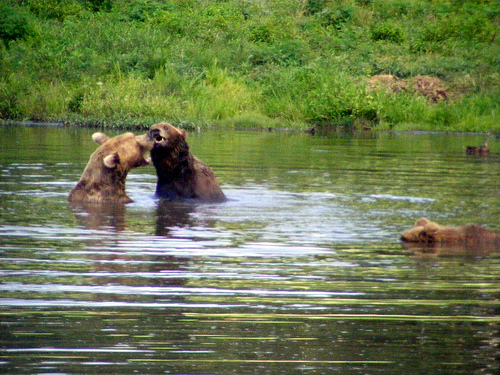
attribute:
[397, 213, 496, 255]
bear — here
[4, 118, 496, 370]
water — here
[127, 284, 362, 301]
ripple — small, big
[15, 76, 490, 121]
ground — here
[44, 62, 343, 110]
grass — green, short, here, tall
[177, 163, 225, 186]
fur — brown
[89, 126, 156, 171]
head — here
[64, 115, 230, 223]
two bears — here